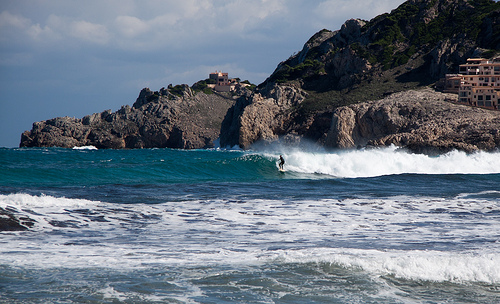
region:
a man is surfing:
[268, 149, 303, 184]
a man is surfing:
[267, 145, 299, 182]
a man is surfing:
[268, 142, 292, 173]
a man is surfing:
[261, 144, 300, 181]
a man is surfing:
[268, 146, 290, 169]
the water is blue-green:
[102, 147, 224, 192]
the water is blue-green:
[97, 147, 215, 185]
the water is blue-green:
[87, 151, 220, 196]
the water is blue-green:
[114, 152, 214, 184]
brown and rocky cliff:
[81, 74, 241, 134]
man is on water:
[277, 160, 291, 169]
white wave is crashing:
[310, 140, 412, 180]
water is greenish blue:
[115, 159, 240, 174]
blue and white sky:
[51, 27, 145, 101]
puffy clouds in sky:
[67, 8, 131, 72]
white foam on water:
[152, 199, 327, 263]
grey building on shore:
[420, 41, 499, 115]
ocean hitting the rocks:
[71, 32, 403, 277]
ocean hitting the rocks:
[57, 12, 410, 257]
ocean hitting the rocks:
[55, 30, 455, 237]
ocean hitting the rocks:
[64, 56, 426, 271]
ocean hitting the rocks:
[38, 0, 431, 271]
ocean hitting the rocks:
[40, 64, 455, 283]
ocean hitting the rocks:
[55, 68, 431, 235]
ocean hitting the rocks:
[59, 39, 481, 236]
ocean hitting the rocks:
[91, 109, 476, 244]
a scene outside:
[5, 5, 492, 295]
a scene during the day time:
[5, 3, 499, 300]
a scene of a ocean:
[3, 3, 498, 288]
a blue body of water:
[1, 140, 491, 302]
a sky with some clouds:
[5, 0, 361, 141]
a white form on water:
[16, 188, 493, 298]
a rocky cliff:
[17, 5, 497, 187]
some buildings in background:
[172, 43, 496, 131]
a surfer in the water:
[265, 122, 294, 178]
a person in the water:
[260, 131, 329, 208]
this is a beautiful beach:
[211, 155, 233, 200]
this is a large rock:
[161, 87, 324, 188]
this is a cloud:
[120, 62, 131, 73]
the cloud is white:
[77, 67, 170, 133]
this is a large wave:
[265, 150, 360, 178]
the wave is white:
[279, 139, 458, 204]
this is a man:
[268, 144, 293, 188]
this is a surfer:
[266, 147, 342, 209]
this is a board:
[260, 126, 294, 188]